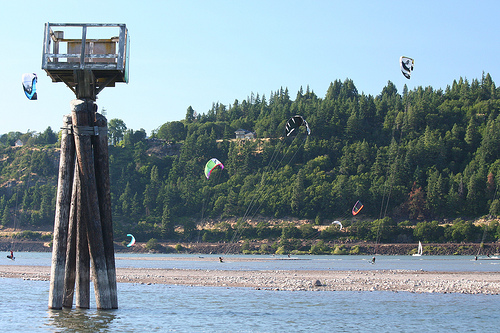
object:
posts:
[45, 98, 119, 310]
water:
[0, 276, 500, 333]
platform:
[38, 21, 133, 86]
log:
[69, 99, 112, 310]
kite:
[202, 157, 224, 178]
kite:
[284, 114, 312, 136]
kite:
[398, 55, 415, 80]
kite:
[350, 199, 366, 216]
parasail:
[203, 157, 225, 180]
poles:
[45, 95, 117, 311]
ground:
[0, 136, 500, 249]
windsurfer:
[411, 240, 423, 257]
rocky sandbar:
[115, 267, 500, 294]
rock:
[313, 279, 323, 285]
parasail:
[124, 232, 138, 249]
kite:
[19, 70, 39, 102]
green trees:
[111, 70, 500, 213]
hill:
[0, 70, 499, 227]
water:
[0, 248, 497, 332]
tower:
[37, 19, 129, 313]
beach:
[0, 256, 499, 295]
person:
[218, 256, 223, 263]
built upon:
[151, 70, 500, 136]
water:
[0, 271, 500, 333]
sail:
[418, 240, 423, 254]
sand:
[346, 270, 500, 295]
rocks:
[414, 278, 474, 294]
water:
[0, 290, 499, 333]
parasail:
[19, 72, 40, 100]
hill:
[0, 80, 497, 243]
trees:
[335, 110, 492, 209]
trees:
[246, 141, 396, 211]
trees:
[217, 76, 402, 139]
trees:
[417, 70, 499, 120]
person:
[10, 250, 13, 259]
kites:
[21, 55, 416, 217]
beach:
[0, 263, 499, 295]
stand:
[42, 21, 128, 92]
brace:
[46, 99, 118, 310]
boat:
[411, 240, 423, 256]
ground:
[0, 215, 500, 297]